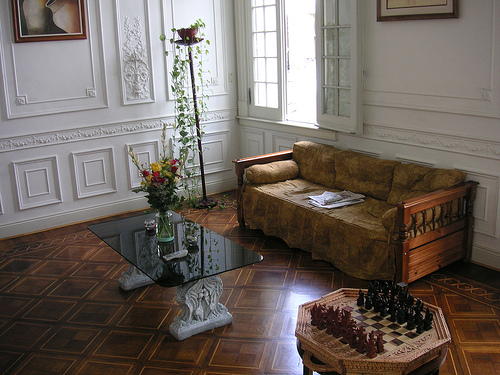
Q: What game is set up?
A: Chess.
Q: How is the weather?
A: Sunny.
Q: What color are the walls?
A: White.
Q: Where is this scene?
A: The living room.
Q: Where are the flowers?
A: In a vase on the table.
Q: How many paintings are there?
A: Two.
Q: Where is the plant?
A: Near the window.